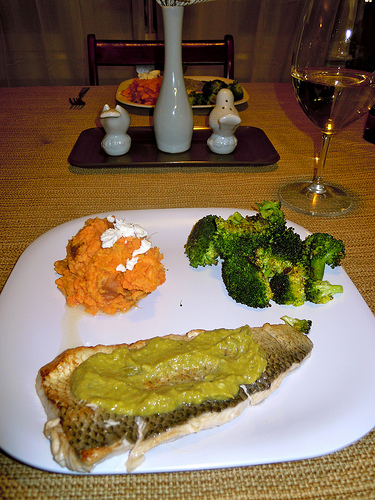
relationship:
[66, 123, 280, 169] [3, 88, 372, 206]
tray on table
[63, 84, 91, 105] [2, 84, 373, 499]
fork on table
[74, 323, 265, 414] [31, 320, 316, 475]
sauce on fish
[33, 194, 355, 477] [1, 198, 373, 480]
meal on plate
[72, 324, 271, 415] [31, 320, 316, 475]
mustard sauce on fish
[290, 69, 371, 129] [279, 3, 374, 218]
wine in glass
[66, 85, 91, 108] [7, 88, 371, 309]
fork on tablecloth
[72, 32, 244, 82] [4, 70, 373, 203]
chair at table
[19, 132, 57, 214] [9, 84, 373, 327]
table cloth on table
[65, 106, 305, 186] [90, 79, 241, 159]
tray holding shakers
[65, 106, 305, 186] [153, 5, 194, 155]
tray holding porcelain vase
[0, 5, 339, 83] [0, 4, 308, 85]
curtains at window